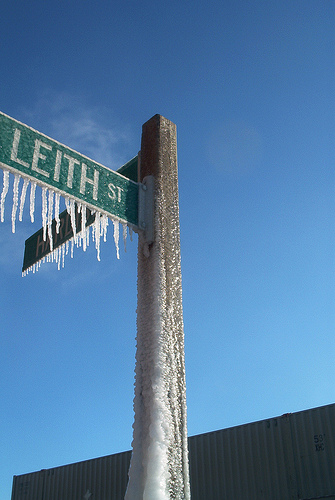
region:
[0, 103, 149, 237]
a green street sign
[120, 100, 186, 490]
a tall metal pole.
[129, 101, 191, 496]
A pole with ice on it.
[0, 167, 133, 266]
ice on a green sign.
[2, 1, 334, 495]
a dark blue sky.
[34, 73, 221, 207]
hazy in a blue sky.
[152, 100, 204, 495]
a think layer of ice.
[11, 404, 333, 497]
a building near a sing.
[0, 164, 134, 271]
ice sickle on a sign.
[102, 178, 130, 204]
st written in print.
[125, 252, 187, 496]
Ice on the pole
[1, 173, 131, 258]
Icicle's hanging from the sign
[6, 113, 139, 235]
The sign say's Lieth St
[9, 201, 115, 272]
Another sign facing a different way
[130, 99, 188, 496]
The steel pole is gray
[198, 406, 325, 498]
The building is gray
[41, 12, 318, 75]
The sky is clear and blue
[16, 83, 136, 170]
There's a small patch of white clouds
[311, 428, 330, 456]
Black writing on the wall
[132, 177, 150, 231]
The bolts holding the sign together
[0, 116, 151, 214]
A sign covered with ice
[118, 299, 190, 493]
A pole covered with ice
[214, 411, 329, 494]
A metal boxcar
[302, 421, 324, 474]
Numbers on boxcar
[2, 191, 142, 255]
Icicles hanging from green sign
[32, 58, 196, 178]
Very few clouds in the sky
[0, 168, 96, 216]
Sign is frozen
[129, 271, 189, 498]
Ice has encase the pole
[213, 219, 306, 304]
Sky is very blue today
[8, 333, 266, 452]
Beautiful day in the winter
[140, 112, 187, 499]
Pole covered by snow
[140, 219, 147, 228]
Small screw on street sign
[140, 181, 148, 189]
Small screw on street sign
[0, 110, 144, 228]
Green street sign on pole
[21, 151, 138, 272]
Green street sign on pole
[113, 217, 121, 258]
Icicle on green street sign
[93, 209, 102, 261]
Icicle on green street sign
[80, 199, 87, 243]
Icicle on green street sign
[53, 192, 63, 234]
Icicle on green street sign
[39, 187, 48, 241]
Icicle on green street sign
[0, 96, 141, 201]
green metal street name sign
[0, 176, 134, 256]
icicles hanging from street sign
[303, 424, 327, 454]
writing on metal siding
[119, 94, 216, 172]
rusted metal street sign pole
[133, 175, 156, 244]
metal bracket securing sign to pole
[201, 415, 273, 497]
beige metal siding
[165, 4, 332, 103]
clear blue cloudless sky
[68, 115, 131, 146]
small cloud in sky behind sign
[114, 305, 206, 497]
metal street sign post covered in frost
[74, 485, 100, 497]
design on metal siding